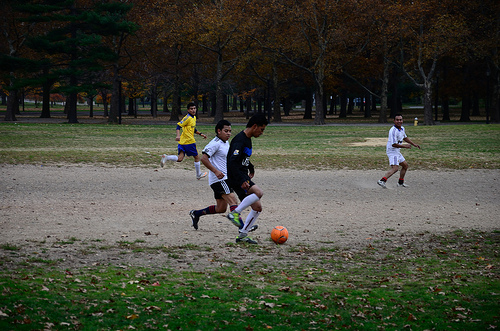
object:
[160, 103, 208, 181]
men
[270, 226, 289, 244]
ball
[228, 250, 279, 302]
leave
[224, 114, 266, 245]
man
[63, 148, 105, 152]
stripe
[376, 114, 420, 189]
boy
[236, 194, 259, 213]
sock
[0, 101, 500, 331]
area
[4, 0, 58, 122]
tree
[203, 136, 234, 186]
clothe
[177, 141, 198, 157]
short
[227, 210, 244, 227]
boot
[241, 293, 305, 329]
grass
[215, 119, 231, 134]
hair